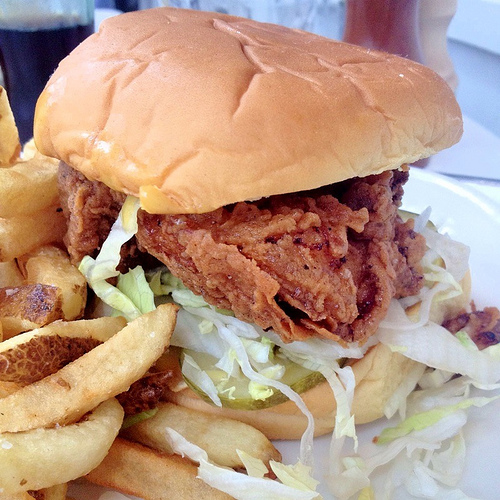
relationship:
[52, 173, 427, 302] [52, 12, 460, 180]
chicken under bun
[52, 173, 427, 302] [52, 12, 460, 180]
chicken below bun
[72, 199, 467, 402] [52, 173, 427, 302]
lettuce under chicken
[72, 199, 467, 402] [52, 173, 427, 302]
lettuce below chicken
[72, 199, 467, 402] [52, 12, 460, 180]
lettuce below bun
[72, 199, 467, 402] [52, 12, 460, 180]
lettuce under bun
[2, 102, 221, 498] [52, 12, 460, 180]
fries beside bun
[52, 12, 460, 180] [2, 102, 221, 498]
bun beside fries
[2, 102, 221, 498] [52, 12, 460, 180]
fries near bun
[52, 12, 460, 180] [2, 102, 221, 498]
bun near fries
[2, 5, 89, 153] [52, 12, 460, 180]
cup behind bun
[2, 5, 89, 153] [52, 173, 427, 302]
cup behind chicken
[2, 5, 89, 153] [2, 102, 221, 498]
cup behind fries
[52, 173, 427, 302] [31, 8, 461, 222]
chicken between bun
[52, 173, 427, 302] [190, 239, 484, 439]
chicken between bread